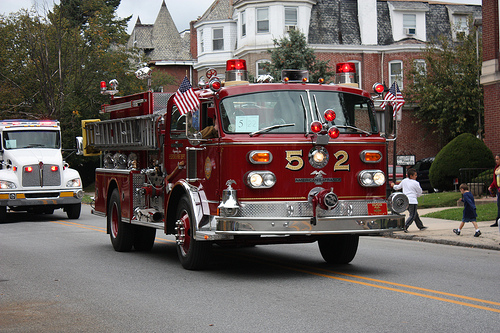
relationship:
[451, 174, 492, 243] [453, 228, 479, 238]
boy wearing sneakers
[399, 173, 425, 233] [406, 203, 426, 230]
boy wearing black pants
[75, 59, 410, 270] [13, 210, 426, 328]
fire truck driving down street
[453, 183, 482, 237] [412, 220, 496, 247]
boy walking on sidewalk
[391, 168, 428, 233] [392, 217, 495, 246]
boy on sidewalk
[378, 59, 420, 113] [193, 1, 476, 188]
window on a house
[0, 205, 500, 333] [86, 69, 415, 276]
ground with truck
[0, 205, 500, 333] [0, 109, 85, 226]
ground with truck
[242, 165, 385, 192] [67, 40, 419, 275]
lights on truck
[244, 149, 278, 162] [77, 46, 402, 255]
light on fire truck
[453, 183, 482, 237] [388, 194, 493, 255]
boy playing on a sidewalk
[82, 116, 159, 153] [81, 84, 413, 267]
ladder on side of a truck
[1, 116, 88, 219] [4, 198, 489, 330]
vehicle on street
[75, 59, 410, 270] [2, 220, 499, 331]
fire truck in street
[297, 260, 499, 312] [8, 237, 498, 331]
lines painted in street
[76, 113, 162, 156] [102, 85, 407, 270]
ladder on fire truck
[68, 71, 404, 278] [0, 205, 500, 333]
fire truck driving down ground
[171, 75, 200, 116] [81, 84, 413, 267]
american flag hanging from truck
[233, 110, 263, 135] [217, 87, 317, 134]
sign in window